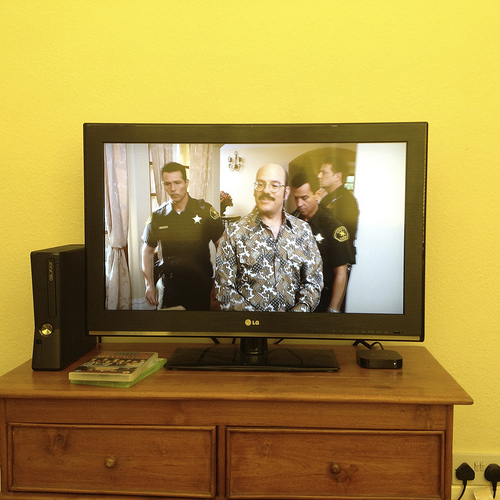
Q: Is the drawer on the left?
A: Yes, the drawer is on the left of the image.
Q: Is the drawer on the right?
A: No, the drawer is on the left of the image.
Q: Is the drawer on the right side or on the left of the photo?
A: The drawer is on the left of the image.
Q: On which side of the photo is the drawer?
A: The drawer is on the left of the image.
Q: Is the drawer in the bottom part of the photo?
A: Yes, the drawer is in the bottom of the image.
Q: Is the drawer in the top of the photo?
A: No, the drawer is in the bottom of the image.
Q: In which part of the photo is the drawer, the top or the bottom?
A: The drawer is in the bottom of the image.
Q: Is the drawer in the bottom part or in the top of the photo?
A: The drawer is in the bottom of the image.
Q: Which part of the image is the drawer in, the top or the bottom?
A: The drawer is in the bottom of the image.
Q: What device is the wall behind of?
A: The wall is behind the TV.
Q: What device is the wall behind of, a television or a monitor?
A: The wall is behind a television.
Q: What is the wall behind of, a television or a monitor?
A: The wall is behind a television.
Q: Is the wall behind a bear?
A: No, the wall is behind the television.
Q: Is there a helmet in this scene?
A: No, there are no helmets.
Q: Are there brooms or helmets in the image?
A: No, there are no helmets or brooms.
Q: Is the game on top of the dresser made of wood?
A: Yes, the game is on top of the dresser.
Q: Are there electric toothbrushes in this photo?
A: No, there are no electric toothbrushes.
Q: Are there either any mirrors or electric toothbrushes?
A: No, there are no electric toothbrushes or mirrors.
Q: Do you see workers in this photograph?
A: No, there are no workers.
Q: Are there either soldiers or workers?
A: No, there are no workers or soldiers.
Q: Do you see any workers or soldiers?
A: No, there are no workers or soldiers.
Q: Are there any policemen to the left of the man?
A: Yes, there is a policeman to the left of the man.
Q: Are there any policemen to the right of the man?
A: No, the policeman is to the left of the man.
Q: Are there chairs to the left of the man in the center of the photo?
A: No, there is a policeman to the left of the man.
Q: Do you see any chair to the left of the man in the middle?
A: No, there is a policeman to the left of the man.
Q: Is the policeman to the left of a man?
A: Yes, the policeman is to the left of a man.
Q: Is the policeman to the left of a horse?
A: No, the policeman is to the left of a man.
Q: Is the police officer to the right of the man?
A: No, the police officer is to the left of the man.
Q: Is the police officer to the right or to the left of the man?
A: The police officer is to the left of the man.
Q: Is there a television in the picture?
A: Yes, there is a television.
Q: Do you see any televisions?
A: Yes, there is a television.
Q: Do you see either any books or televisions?
A: Yes, there is a television.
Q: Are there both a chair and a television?
A: No, there is a television but no chairs.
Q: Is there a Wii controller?
A: No, there are no Wii controllers.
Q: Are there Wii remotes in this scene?
A: No, there are no Wii remotes.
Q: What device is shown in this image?
A: The device is a television.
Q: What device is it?
A: The device is a television.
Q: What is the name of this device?
A: This is a television.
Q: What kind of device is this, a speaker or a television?
A: This is a television.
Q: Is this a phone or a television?
A: This is a television.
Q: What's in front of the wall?
A: The television is in front of the wall.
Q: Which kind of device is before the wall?
A: The device is a television.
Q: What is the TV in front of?
A: The TV is in front of the wall.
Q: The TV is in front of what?
A: The TV is in front of the wall.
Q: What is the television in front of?
A: The TV is in front of the wall.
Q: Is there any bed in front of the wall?
A: No, there is a television in front of the wall.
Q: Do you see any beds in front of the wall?
A: No, there is a television in front of the wall.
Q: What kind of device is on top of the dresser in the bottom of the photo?
A: The device is a television.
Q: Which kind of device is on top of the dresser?
A: The device is a television.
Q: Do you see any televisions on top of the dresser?
A: Yes, there is a television on top of the dresser.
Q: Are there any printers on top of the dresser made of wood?
A: No, there is a television on top of the dresser.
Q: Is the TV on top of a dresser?
A: Yes, the TV is on top of a dresser.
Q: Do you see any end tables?
A: No, there are no end tables.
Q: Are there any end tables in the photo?
A: No, there are no end tables.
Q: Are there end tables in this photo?
A: No, there are no end tables.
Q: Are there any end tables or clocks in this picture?
A: No, there are no end tables or clocks.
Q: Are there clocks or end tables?
A: No, there are no end tables or clocks.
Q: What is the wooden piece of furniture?
A: The piece of furniture is a dresser.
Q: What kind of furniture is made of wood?
A: The furniture is a dresser.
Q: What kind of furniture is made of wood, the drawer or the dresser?
A: The dresser is made of wood.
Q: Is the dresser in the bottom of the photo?
A: Yes, the dresser is in the bottom of the image.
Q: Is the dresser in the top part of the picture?
A: No, the dresser is in the bottom of the image.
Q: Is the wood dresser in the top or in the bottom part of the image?
A: The dresser is in the bottom of the image.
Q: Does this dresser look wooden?
A: Yes, the dresser is wooden.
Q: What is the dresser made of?
A: The dresser is made of wood.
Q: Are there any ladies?
A: No, there are no ladies.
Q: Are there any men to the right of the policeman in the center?
A: Yes, there is a man to the right of the police officer.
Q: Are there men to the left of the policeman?
A: No, the man is to the right of the policeman.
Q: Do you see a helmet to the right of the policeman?
A: No, there is a man to the right of the policeman.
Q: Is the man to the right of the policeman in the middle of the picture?
A: Yes, the man is to the right of the policeman.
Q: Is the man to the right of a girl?
A: No, the man is to the right of the policeman.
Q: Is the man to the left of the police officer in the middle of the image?
A: No, the man is to the right of the police officer.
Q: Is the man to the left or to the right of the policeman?
A: The man is to the right of the policeman.